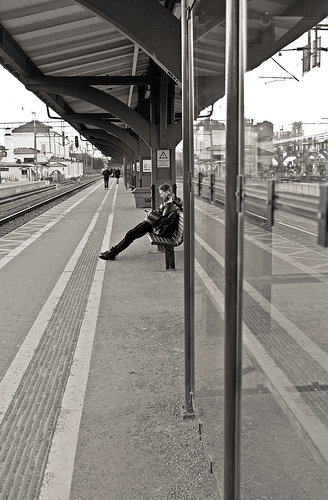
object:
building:
[0, 120, 83, 182]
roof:
[12, 120, 56, 133]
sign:
[157, 150, 170, 168]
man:
[102, 166, 111, 187]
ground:
[34, 285, 56, 372]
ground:
[78, 284, 174, 394]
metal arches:
[25, 85, 151, 160]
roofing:
[0, 0, 328, 157]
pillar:
[151, 148, 177, 207]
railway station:
[0, 0, 326, 500]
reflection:
[188, 121, 272, 337]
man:
[99, 183, 175, 260]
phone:
[145, 210, 147, 213]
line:
[0, 178, 119, 500]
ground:
[3, 171, 325, 494]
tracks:
[0, 174, 104, 225]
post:
[151, 184, 156, 209]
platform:
[0, 177, 328, 500]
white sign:
[143, 160, 152, 172]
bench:
[147, 212, 184, 270]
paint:
[97, 202, 105, 210]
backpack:
[152, 209, 178, 236]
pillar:
[134, 160, 139, 188]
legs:
[116, 225, 146, 253]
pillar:
[139, 140, 151, 187]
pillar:
[224, 0, 247, 500]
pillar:
[182, 0, 195, 412]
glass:
[190, 0, 328, 500]